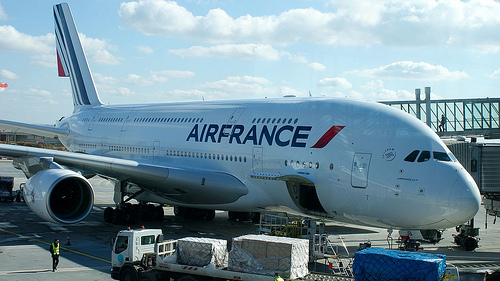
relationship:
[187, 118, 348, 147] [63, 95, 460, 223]
logo on side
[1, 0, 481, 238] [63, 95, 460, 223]
airplane has side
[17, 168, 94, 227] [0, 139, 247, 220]
engine under wing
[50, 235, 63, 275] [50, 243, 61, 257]
man in vest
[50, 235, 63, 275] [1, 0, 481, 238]
man near plane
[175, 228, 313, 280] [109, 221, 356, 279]
cargo on truck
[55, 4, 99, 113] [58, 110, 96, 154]
tail on back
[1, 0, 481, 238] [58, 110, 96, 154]
plane has back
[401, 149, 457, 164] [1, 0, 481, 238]
cockpit on plane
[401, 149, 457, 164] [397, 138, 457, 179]
cockpit for cockpit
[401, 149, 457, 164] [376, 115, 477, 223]
cockpit on front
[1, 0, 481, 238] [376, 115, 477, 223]
plane has front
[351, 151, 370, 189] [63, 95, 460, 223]
door on side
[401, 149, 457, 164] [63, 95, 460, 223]
cockpit on side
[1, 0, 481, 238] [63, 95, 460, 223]
plane has side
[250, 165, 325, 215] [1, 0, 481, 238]
cargo door on plane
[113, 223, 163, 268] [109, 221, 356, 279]
cab on truck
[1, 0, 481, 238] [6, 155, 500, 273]
plane sitting on ground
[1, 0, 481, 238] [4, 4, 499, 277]
airplane at airport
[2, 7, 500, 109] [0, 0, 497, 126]
clouds in sky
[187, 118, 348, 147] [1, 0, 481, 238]
writing on airplane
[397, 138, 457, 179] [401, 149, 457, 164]
cockpit has cockpit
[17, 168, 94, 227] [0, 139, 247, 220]
engine underneath wing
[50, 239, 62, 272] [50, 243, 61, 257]
man in vest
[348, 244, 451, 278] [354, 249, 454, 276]
luggage carrier covered in blue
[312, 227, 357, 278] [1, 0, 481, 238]
walkway to airplane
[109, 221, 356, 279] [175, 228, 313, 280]
truck hauling cargo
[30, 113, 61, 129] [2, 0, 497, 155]
hills in distance